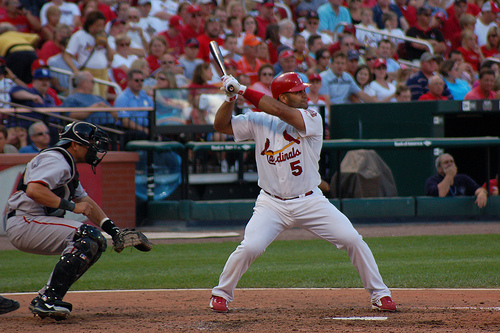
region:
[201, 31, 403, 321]
a baseball player gets ready to hit a ball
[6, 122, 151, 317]
the catcher is behind the baseball player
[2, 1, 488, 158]
spectators are behind the baseball player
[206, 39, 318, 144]
the player is holding a bat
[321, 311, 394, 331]
the player is standing next to home plate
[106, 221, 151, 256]
the catcher is wearing a mitt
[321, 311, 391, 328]
the catcher is crouched behind home plate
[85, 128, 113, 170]
the catcher is wearing a face mask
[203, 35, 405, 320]
the player is on the Cardinals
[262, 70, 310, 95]
the player has a helmet on his head.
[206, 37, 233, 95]
The batter is holding a black bat.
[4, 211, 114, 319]
The catcher is wearing grey pants.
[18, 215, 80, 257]
The catcher has a red stripe on his pants.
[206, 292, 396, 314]
The catcher is wearing red shoes.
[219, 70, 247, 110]
The batter is wearing white gloves.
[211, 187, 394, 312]
The batter is wearing white pants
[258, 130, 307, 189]
The front of the batters shirt indicates he is on the team called Cardinals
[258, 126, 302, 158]
The batter's shirt has two red birds on it.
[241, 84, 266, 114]
The batter is wearing a red wrist band.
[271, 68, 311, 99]
The batter is wearing a red helmet.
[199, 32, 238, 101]
a black baseball bat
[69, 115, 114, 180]
a black catchers mask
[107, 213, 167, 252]
a dirty black catching mit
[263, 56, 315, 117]
a hard red helmet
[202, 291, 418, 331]
red and white cleats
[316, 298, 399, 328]
home plate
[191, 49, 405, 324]
a white cardinals baseball jersey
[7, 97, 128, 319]
a grey and red baseball uniform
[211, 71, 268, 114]
white baseball gloves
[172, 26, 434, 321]
Baseball player in position to hit the ball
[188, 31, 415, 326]
Player holds the bat on his right side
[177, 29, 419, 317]
Baseball player has the knees bended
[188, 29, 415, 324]
Player has a red helmet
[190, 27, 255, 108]
Bat is black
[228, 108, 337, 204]
Shirt number is 5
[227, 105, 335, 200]
Shirt has the name of team "Cardinals"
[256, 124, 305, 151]
Two red bird painted on shirt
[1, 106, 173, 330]
Catcher is crouched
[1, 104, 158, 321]
Player has a black helmet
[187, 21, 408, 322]
Batter holding the bat over his right shoulder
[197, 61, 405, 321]
Batter wearing a red hat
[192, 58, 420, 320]
Baseball player wearing a team uniform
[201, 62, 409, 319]
Team uniform is white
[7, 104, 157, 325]
Catcher is crouched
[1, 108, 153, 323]
Catcher wears a black helmet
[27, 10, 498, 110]
Bleachers are filled with viewers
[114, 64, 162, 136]
Man wearing blue shirt and glasses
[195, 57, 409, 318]
Baseball player is number 5